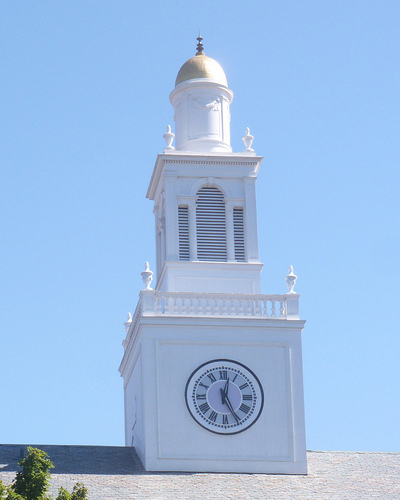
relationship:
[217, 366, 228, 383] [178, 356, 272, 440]
number 12 on clock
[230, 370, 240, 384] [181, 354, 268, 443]
number on clock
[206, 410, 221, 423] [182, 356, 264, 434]
number 7 of clock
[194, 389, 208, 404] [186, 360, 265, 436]
number on clock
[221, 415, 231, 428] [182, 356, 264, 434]
number 6 on clock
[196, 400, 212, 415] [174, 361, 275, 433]
number 8 on clock